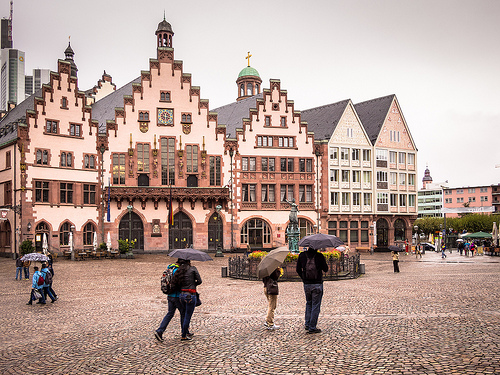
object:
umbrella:
[298, 232, 337, 250]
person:
[40, 262, 58, 306]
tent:
[459, 229, 496, 254]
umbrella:
[20, 251, 50, 262]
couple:
[261, 247, 329, 334]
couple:
[26, 262, 60, 308]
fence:
[228, 247, 361, 282]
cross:
[243, 51, 254, 66]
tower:
[234, 49, 262, 101]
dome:
[236, 65, 260, 78]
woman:
[260, 266, 283, 331]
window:
[159, 137, 167, 145]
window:
[62, 152, 67, 166]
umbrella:
[387, 241, 405, 252]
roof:
[298, 99, 350, 141]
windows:
[60, 191, 68, 204]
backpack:
[300, 255, 319, 275]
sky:
[0, 0, 500, 191]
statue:
[285, 197, 300, 235]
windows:
[67, 191, 73, 204]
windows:
[183, 146, 191, 154]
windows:
[352, 191, 359, 205]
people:
[294, 247, 328, 332]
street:
[0, 248, 500, 374]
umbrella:
[165, 243, 215, 261]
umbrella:
[255, 244, 287, 279]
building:
[0, 8, 418, 261]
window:
[119, 170, 126, 183]